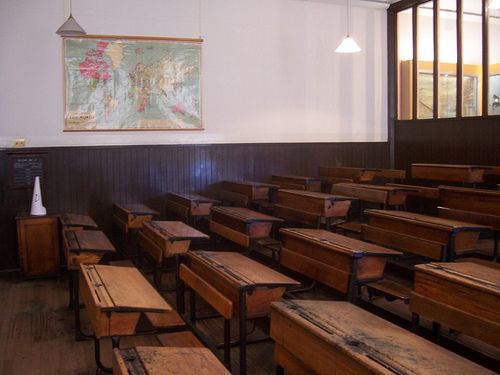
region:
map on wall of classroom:
[48, 23, 222, 139]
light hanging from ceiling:
[324, 0, 376, 67]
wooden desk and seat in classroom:
[73, 250, 239, 373]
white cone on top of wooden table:
[18, 172, 53, 218]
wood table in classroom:
[10, 210, 66, 284]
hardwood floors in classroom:
[5, 275, 99, 372]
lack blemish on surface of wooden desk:
[332, 324, 375, 357]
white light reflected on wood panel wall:
[183, 148, 225, 184]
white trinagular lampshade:
[330, 34, 363, 55]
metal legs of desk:
[90, 338, 118, 374]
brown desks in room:
[77, 159, 494, 341]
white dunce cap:
[18, 176, 53, 213]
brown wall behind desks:
[85, 151, 270, 211]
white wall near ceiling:
[250, 17, 300, 124]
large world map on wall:
[49, 35, 229, 129]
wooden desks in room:
[125, 181, 471, 373]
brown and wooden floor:
[5, 288, 85, 374]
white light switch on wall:
[6, 133, 40, 148]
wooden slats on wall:
[397, 6, 497, 121]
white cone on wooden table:
[20, 168, 52, 218]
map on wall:
[47, 24, 217, 139]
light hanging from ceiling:
[330, 2, 364, 60]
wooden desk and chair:
[69, 255, 244, 372]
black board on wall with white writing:
[5, 150, 50, 193]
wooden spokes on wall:
[382, 3, 498, 165]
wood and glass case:
[396, 53, 481, 122]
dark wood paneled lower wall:
[15, 143, 387, 266]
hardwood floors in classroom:
[6, 268, 483, 373]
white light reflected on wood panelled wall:
[184, 149, 224, 179]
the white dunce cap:
[30, 175, 46, 215]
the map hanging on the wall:
[60, 36, 204, 132]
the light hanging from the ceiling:
[336, 0, 360, 52]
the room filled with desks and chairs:
[55, 156, 498, 373]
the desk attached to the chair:
[77, 260, 234, 371]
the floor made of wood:
[2, 212, 494, 370]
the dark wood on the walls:
[0, 4, 499, 280]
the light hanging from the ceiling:
[55, 0, 86, 37]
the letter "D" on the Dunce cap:
[33, 192, 39, 202]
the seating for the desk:
[138, 262, 230, 350]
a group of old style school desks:
[57, 159, 498, 374]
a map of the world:
[62, 32, 203, 134]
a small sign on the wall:
[7, 152, 47, 189]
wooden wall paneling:
[1, 140, 393, 272]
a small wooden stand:
[18, 210, 63, 280]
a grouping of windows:
[389, 0, 499, 122]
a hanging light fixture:
[56, 2, 86, 39]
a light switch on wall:
[10, 137, 28, 149]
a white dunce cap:
[27, 174, 48, 216]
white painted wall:
[0, 5, 388, 148]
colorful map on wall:
[59, 26, 210, 128]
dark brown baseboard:
[4, 152, 406, 277]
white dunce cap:
[22, 170, 54, 219]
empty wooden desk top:
[78, 257, 173, 350]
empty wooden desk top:
[184, 230, 294, 327]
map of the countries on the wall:
[59, 36, 203, 135]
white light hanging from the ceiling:
[332, 2, 360, 59]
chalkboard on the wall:
[4, 155, 46, 178]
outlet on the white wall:
[10, 135, 26, 149]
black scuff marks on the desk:
[356, 323, 394, 357]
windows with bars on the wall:
[396, 9, 496, 121]